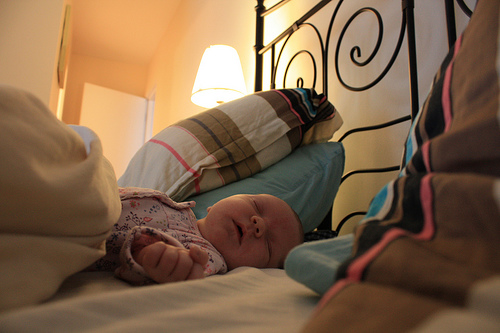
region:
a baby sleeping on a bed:
[99, 171, 316, 293]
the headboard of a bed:
[251, 0, 438, 96]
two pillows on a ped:
[183, 102, 350, 207]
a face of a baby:
[213, 196, 290, 259]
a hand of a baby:
[134, 238, 213, 283]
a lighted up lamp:
[183, 32, 248, 119]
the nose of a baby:
[247, 208, 276, 243]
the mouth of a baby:
[228, 213, 250, 253]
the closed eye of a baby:
[261, 232, 278, 259]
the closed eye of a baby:
[245, 194, 268, 216]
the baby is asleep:
[115, 182, 297, 282]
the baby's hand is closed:
[138, 238, 209, 280]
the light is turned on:
[187, 40, 249, 112]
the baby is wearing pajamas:
[99, 184, 219, 286]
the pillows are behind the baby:
[117, 88, 343, 263]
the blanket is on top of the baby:
[0, 84, 119, 306]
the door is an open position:
[80, 80, 158, 200]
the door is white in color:
[76, 81, 160, 186]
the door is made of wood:
[75, 81, 149, 181]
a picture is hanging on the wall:
[54, 3, 72, 88]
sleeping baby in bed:
[92, 146, 301, 273]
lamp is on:
[183, 36, 250, 103]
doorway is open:
[34, 53, 82, 133]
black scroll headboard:
[244, 8, 497, 245]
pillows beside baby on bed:
[93, 86, 373, 234]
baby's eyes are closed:
[109, 171, 303, 279]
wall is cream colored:
[4, 8, 66, 107]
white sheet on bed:
[24, 276, 392, 331]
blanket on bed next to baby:
[0, 81, 122, 308]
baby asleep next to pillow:
[113, 164, 300, 277]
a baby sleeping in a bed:
[17, 46, 497, 318]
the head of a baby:
[196, 189, 303, 271]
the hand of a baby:
[132, 236, 209, 285]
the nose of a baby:
[249, 214, 269, 237]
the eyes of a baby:
[251, 199, 276, 265]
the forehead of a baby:
[267, 193, 306, 275]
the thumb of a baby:
[186, 243, 213, 260]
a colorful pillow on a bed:
[108, 85, 330, 202]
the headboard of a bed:
[237, 0, 457, 190]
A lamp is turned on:
[190, 40, 246, 112]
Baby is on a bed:
[98, 172, 308, 327]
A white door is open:
[77, 79, 153, 189]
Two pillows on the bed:
[115, 86, 347, 239]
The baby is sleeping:
[93, 183, 306, 287]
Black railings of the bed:
[252, 1, 482, 240]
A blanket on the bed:
[1, 81, 121, 320]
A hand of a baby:
[139, 233, 214, 289]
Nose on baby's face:
[246, 211, 269, 241]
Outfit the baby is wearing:
[115, 183, 230, 287]